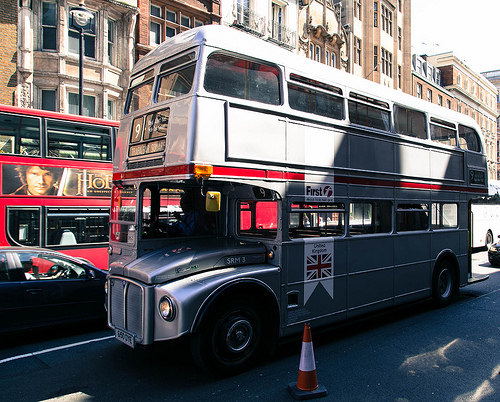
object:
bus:
[1, 104, 125, 335]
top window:
[203, 47, 283, 107]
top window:
[287, 72, 345, 122]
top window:
[348, 84, 393, 133]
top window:
[392, 97, 428, 142]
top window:
[428, 111, 458, 150]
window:
[460, 126, 480, 150]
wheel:
[191, 282, 282, 372]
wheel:
[426, 243, 470, 308]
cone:
[287, 320, 328, 400]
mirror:
[204, 190, 224, 213]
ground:
[343, 105, 385, 135]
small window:
[387, 104, 430, 141]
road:
[0, 253, 499, 398]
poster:
[303, 167, 336, 204]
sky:
[407, 5, 497, 77]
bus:
[101, 24, 489, 377]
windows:
[291, 201, 465, 242]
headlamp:
[156, 295, 176, 322]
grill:
[106, 273, 145, 338]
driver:
[168, 188, 213, 239]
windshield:
[106, 182, 139, 242]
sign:
[304, 167, 337, 204]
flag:
[302, 236, 333, 305]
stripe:
[107, 164, 488, 193]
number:
[224, 254, 250, 269]